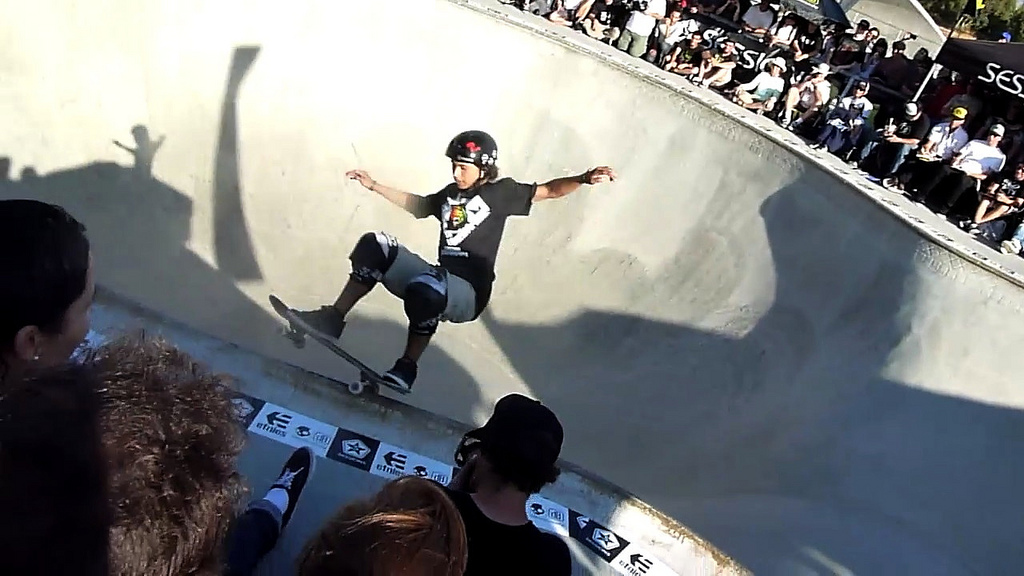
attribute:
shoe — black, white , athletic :
[380, 350, 420, 392]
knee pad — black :
[389, 264, 456, 328]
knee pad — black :
[339, 226, 400, 293]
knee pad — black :
[392, 257, 466, 365]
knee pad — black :
[396, 251, 463, 341]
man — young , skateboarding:
[272, 102, 627, 397]